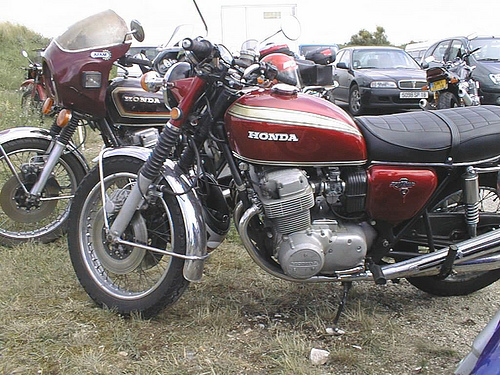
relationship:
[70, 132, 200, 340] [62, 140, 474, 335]
tire on cycle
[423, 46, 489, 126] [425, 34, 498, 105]
cycle near car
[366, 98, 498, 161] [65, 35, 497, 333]
seat on bike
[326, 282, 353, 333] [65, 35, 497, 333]
kick stand on bike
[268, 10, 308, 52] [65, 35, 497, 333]
mirror on bike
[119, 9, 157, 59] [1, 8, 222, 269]
mirror on cycle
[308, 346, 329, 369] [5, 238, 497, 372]
rock in grass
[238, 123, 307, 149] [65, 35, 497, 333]
brand on bike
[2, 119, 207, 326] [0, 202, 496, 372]
wheels in grass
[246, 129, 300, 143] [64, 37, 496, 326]
honda on bike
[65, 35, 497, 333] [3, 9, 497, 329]
bike in lot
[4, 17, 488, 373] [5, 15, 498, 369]
grass in area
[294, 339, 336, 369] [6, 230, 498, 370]
rock on ground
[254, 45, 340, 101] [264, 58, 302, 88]
helmet with shield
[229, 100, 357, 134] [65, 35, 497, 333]
stripe on bike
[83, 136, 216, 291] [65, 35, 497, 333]
fender on bike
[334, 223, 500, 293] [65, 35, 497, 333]
muffler on bike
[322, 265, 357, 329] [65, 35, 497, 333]
kick stand on bike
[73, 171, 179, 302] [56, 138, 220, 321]
spokes on wheel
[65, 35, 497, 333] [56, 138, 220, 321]
bike has wheel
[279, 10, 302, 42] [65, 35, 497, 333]
mirror on bike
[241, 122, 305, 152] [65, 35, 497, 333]
honda on bike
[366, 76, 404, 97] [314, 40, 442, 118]
headlight on car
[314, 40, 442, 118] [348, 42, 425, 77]
car has window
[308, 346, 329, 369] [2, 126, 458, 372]
rock on grass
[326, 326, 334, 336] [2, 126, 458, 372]
rock on grass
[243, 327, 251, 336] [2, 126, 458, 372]
rock on grass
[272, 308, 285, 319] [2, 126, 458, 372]
rock on grass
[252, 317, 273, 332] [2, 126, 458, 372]
rock on grass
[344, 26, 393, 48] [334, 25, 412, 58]
leaves on tree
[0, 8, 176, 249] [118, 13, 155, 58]
cycle has mirror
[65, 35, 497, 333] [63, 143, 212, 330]
bike has wheel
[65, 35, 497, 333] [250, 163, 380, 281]
bike has motor